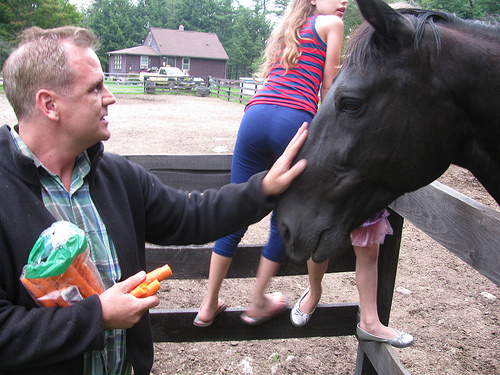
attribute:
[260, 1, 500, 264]
horse — black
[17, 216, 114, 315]
bag — carrots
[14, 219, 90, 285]
top — green, tank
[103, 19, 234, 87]
house — brown, small, red, background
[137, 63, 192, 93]
truck — pickup, yellow, parked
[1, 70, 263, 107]
fence — wooden, grey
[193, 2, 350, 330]
girl — young, climbing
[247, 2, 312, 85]
hair — long, blonde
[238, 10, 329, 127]
top — red, blue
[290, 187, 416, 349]
girl — hidden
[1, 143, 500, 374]
fence — wood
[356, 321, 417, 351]
shoes — silver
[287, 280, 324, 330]
shoes — silver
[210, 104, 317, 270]
pants — blue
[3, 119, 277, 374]
jacket — black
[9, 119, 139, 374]
shirt — blue plaid